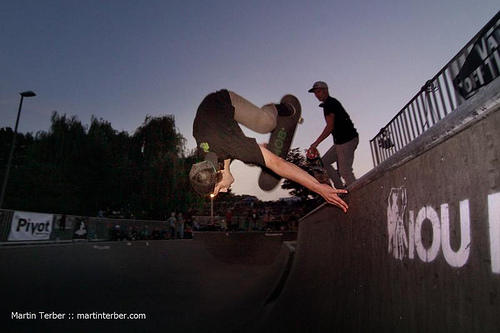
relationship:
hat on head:
[184, 148, 228, 202] [186, 142, 246, 202]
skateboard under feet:
[250, 87, 312, 194] [268, 99, 298, 122]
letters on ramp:
[394, 205, 415, 261] [4, 88, 498, 328]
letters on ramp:
[411, 204, 443, 262] [4, 88, 498, 328]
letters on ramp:
[435, 191, 481, 271] [4, 88, 498, 328]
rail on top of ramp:
[369, 0, 498, 170] [4, 88, 498, 328]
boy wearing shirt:
[306, 80, 360, 190] [317, 95, 363, 147]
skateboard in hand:
[307, 148, 330, 188] [304, 144, 318, 158]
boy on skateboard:
[184, 87, 355, 224] [250, 81, 304, 188]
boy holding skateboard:
[306, 79, 364, 215] [304, 149, 332, 193]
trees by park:
[4, 103, 216, 217] [4, 77, 495, 329]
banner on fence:
[2, 207, 55, 247] [1, 204, 183, 242]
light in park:
[17, 85, 47, 111] [5, 9, 495, 330]